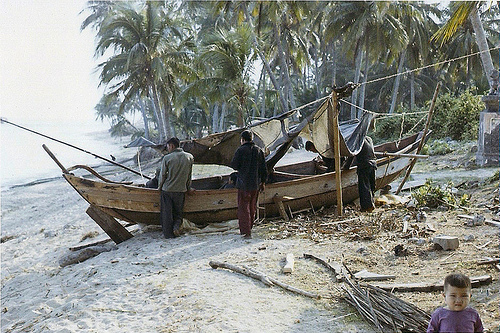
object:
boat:
[61, 129, 432, 231]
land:
[0, 208, 497, 330]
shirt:
[158, 147, 194, 192]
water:
[23, 122, 110, 167]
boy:
[423, 273, 484, 332]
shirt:
[427, 308, 482, 333]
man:
[231, 130, 269, 239]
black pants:
[160, 191, 186, 237]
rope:
[353, 44, 498, 86]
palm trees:
[80, 0, 500, 144]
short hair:
[444, 273, 470, 288]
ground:
[291, 224, 451, 325]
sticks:
[341, 282, 416, 331]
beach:
[1, 14, 156, 321]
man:
[344, 134, 378, 212]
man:
[158, 137, 195, 239]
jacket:
[229, 141, 268, 191]